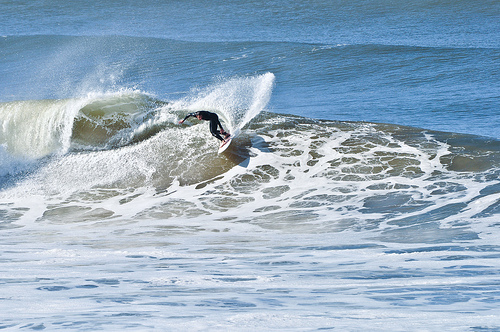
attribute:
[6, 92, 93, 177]
wave — white, big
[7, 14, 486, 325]
ocean — clear, blue, white, calm, beautiful, huge, dark blue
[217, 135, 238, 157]
surfboard — white, pink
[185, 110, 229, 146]
man — surfing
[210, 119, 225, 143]
pants — black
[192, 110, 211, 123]
shirt — black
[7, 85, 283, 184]
waves — gray, white, blue, big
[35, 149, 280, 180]
caps — white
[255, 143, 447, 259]
foam — white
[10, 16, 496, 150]
background — calm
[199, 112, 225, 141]
suit — black, wet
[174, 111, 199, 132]
hand — up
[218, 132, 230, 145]
feet — bare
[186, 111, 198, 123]
sleeves — long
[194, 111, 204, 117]
hair — brown